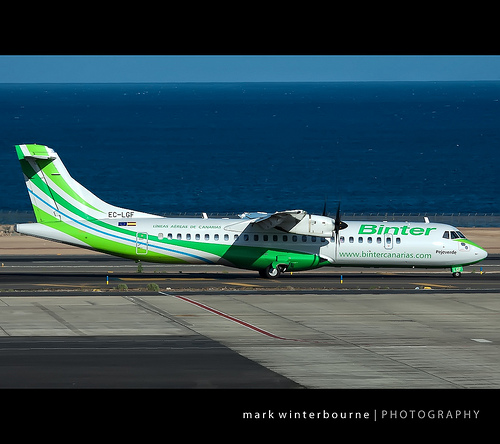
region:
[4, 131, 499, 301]
White and green plane on runway.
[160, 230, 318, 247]
Windows along side of plane.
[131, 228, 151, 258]
Rear passenger door on plane.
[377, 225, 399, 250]
Front passenger door on plane.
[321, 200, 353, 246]
Two black propellers on plane's engine.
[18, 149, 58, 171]
Horizontal stabilizer on plane's tail.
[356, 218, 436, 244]
Name of plane's company written in green.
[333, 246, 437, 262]
Plane's company email address.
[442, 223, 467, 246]
Side and front window of plane's cockpit.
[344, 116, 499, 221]
Water on side of airport runway.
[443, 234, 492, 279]
Nose of a airplane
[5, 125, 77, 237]
Tail wing on airplane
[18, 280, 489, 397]
A airport runway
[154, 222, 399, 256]
Windows on a airplane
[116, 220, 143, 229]
A flag painted on a airplane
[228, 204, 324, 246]
Right wing on a airplane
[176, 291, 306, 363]
A red line painted on a runway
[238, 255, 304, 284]
Wheels on a airplane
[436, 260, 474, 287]
Front landing gear on a airplane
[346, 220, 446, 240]
Letters painted on a airplane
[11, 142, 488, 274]
airplane on a tarmac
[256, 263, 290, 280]
rear landing gear of plane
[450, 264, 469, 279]
front landing gear of plane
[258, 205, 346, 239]
right engine and propeller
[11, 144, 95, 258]
tail of the plane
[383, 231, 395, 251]
front door of plane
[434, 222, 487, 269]
nose of the plane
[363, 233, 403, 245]
first four windows on side of plane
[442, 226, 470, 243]
windshield of the plane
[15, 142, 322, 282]
green and blue stripes on plane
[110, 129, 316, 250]
Blue water by an airplane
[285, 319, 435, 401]
Gray cement on a runway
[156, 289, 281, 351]
Red line on a gray runway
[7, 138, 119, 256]
Green and white plane tail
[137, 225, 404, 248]
Windows on a plane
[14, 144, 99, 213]
Tail on a plane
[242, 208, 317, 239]
Wing on a plane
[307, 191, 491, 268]
Binter written in green on a white plane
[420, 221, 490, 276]
Green and white nose on a plane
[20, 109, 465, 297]
Plane on a runway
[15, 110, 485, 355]
airplane on ground by water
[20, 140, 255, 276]
green and blue stripes across plane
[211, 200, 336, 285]
plane shaded by wing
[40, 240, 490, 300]
darker strip of runway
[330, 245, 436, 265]
company's website on front of plane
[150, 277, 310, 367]
red line on grey ground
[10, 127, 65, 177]
tail bent over to side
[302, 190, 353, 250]
black propellers on plane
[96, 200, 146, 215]
letters separated by hyphen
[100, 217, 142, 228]
red, white and blue flag of country